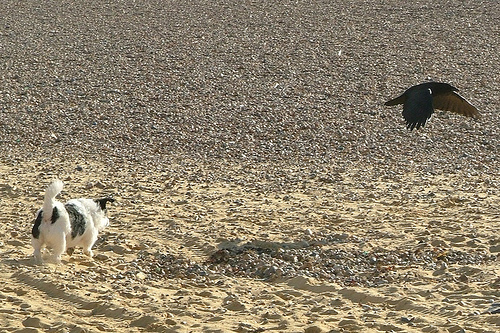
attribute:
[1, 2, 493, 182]
gravel — gray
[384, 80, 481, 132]
bird — black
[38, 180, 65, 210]
tail — white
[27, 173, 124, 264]
dog — white, black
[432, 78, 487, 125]
wing — brown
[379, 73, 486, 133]
bird — brown, black